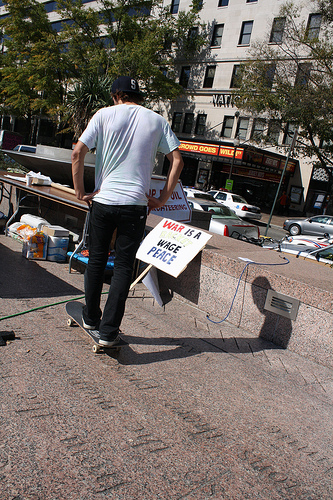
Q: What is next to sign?
A: Guy standing on skateboard.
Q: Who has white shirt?
A: Man standing on skateboard.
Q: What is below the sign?
A: Shadow of man on skateboard.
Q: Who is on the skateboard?
A: Man wearing white t-shirt.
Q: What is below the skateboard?
A: Cement walk with markings.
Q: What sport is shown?
A: Skateboarding.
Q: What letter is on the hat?
A: S.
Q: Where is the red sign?
A: Across the street.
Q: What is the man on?
A: Skateboard.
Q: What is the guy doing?
A: Skateboarding.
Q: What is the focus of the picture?
A: The guy on the skateboard.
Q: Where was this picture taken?
A: At a protest.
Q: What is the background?
A: A city area.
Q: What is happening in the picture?
A: A protest.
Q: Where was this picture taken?
A: In a city.